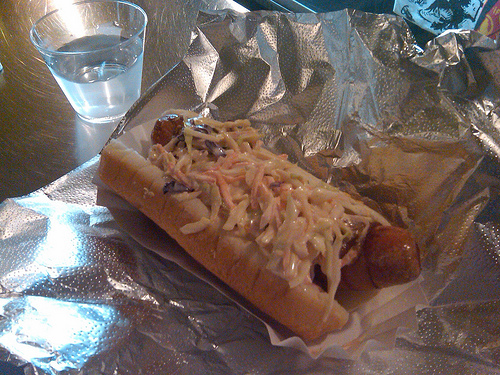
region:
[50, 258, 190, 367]
the foil is silver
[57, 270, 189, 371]
the fpoil is mettalic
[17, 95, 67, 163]
the sufrace is brown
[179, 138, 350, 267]
the cabbage is on the sausage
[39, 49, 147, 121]
the cup has water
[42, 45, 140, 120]
the cup is plastic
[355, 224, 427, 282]
the sausage is brown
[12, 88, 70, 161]
the surface is shiny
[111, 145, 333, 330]
the bread is brown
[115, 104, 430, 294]
mustard is on the sausage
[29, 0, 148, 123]
a plastic cup of water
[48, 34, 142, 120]
water in a cup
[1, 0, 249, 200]
a metal counter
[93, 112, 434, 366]
a paper holder under a hotdog bun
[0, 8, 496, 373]
a sheet of aluminum foil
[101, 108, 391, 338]
a hotdog bun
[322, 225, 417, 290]
a hotdog end sticking out of a bun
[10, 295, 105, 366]
a bright reflection on tinfoil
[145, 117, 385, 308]
coleslaw on top of a hotdog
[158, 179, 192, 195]
a piece of purple cabbage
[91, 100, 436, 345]
Food in the foreground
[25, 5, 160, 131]
A small plastic cup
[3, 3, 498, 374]
Food is on tin foil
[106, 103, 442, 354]
A hot dog on a bun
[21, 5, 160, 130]
Cup is full of water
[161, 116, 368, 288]
Topping is on the hotdog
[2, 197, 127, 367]
Blue light is reflecting off the tin foil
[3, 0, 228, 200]
A metal textured table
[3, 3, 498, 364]
Photo was taken indoors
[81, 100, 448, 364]
A paper object is under the hot dog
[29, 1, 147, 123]
clear cup with water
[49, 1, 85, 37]
light reflection on table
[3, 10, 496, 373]
crumpled surface of tin foil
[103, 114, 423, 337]
hot dog in bun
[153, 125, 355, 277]
cole slaw on top of hot dog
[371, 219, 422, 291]
end of cooked hot dog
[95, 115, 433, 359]
white paper under bun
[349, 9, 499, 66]
crumpled edge of aluminum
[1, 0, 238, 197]
shiny metal table under cup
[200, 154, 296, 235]
shredded carrots in cole slaw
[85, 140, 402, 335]
a hot dog on a table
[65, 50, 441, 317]
a hot dog on a bun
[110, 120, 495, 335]
a hot dog on a table with coldslaw on it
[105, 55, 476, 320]
a hot dog near a cup of water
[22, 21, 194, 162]
a cup of water near a hot dog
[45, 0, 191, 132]
a cup of water on a table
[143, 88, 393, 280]
cold slaw on a hot dog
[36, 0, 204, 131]
a cup that is half full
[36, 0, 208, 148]
a cup that is half empty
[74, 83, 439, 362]
a hot dog sitting on silver a wrapper